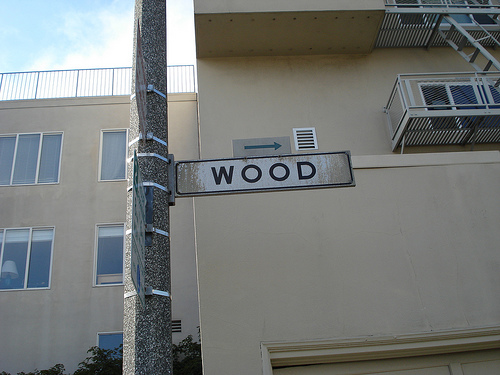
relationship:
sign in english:
[175, 146, 362, 196] [170, 135, 344, 257]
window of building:
[95, 124, 133, 187] [3, 0, 488, 367]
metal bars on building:
[1, 62, 199, 102] [2, 92, 202, 374]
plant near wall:
[73, 343, 120, 372] [3, 89, 200, 371]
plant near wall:
[169, 333, 201, 373] [3, 89, 200, 371]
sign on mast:
[175, 146, 362, 196] [120, 0, 173, 375]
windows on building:
[0, 127, 152, 372] [3, 0, 488, 367]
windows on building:
[392, 0, 499, 131] [3, 0, 488, 367]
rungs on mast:
[121, 81, 172, 304] [120, 0, 173, 375]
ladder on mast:
[436, 14, 500, 95] [120, 0, 173, 375]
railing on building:
[384, 64, 499, 141] [196, 62, 498, 373]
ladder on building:
[436, 14, 498, 94] [191, 0, 497, 371]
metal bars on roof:
[0, 63, 196, 101] [6, 94, 196, 103]